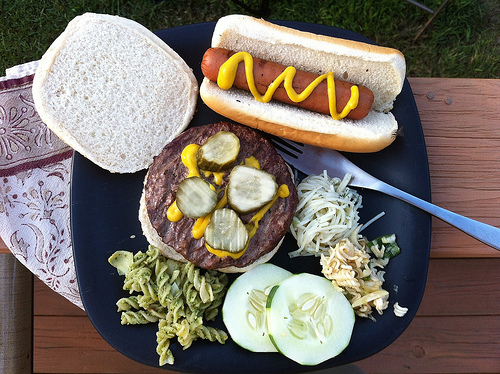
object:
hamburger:
[146, 123, 298, 269]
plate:
[70, 22, 431, 374]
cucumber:
[266, 274, 354, 365]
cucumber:
[222, 263, 295, 353]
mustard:
[163, 144, 290, 259]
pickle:
[225, 165, 278, 211]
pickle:
[198, 129, 241, 170]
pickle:
[174, 178, 218, 218]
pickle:
[204, 208, 250, 254]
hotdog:
[198, 47, 374, 118]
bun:
[200, 14, 403, 155]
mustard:
[216, 51, 358, 119]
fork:
[269, 138, 500, 253]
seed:
[302, 296, 315, 311]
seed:
[286, 326, 305, 338]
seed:
[324, 317, 332, 334]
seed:
[317, 324, 328, 334]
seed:
[313, 301, 325, 319]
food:
[319, 235, 409, 320]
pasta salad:
[109, 245, 229, 367]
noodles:
[287, 170, 385, 256]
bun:
[32, 10, 199, 174]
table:
[31, 76, 499, 373]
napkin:
[0, 59, 87, 312]